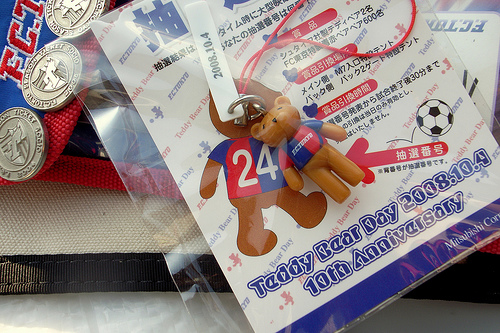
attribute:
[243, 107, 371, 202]
bear — small, plastic, brown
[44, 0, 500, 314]
package — plastic, clear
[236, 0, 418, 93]
string — red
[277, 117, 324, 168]
jersey — red, blue, white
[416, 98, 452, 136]
soccer ball — white, black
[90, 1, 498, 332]
card — white, red, blue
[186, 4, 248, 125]
id tag — white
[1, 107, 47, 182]
coin — silver, small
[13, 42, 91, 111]
coin — silver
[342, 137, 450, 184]
arrow — red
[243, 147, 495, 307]
writing — blue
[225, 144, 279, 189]
number — white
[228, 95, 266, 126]
key chain — small